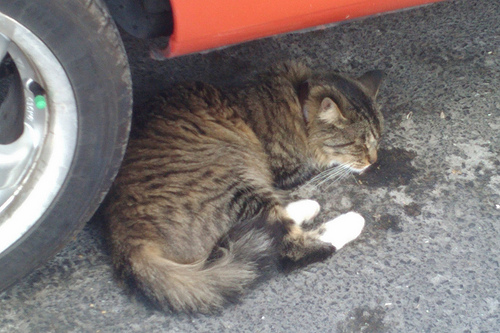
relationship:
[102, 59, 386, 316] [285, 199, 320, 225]
cat with feet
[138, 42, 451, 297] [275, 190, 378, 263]
cat with feet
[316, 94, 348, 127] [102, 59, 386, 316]
ear of cat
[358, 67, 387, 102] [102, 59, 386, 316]
ear of cat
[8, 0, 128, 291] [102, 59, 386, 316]
tire on cat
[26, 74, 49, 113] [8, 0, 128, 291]
air cap on tire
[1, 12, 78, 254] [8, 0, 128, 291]
rim inside tire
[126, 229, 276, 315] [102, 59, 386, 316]
tail of cat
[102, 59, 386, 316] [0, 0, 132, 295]
cat under tire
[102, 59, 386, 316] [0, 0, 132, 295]
cat near tire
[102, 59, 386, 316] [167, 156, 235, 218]
cat with black stripes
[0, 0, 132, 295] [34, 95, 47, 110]
tire has air cap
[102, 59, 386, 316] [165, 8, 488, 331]
cat lying on concrete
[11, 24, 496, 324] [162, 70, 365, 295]
concrete beneath cat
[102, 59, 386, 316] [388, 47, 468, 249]
cat sleeping on ground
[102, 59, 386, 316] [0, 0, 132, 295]
cat sleeping by tire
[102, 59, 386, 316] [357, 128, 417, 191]
cat in spot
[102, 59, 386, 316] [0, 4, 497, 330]
cat lying on a road